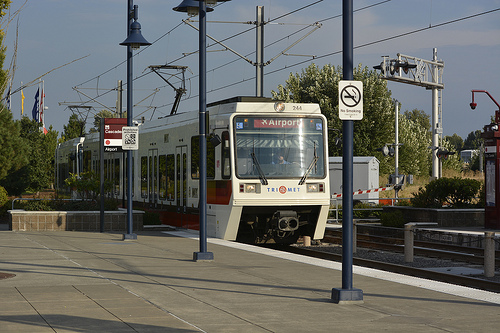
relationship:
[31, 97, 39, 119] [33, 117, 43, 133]
flag from pole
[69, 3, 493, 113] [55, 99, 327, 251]
cord above train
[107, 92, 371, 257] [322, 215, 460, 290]
train travels on tracks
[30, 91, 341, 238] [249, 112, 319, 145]
train has marque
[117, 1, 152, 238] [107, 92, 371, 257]
pole near train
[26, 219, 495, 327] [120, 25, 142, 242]
platform has pole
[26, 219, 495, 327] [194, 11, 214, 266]
platform has pole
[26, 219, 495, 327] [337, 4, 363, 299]
platform has pole